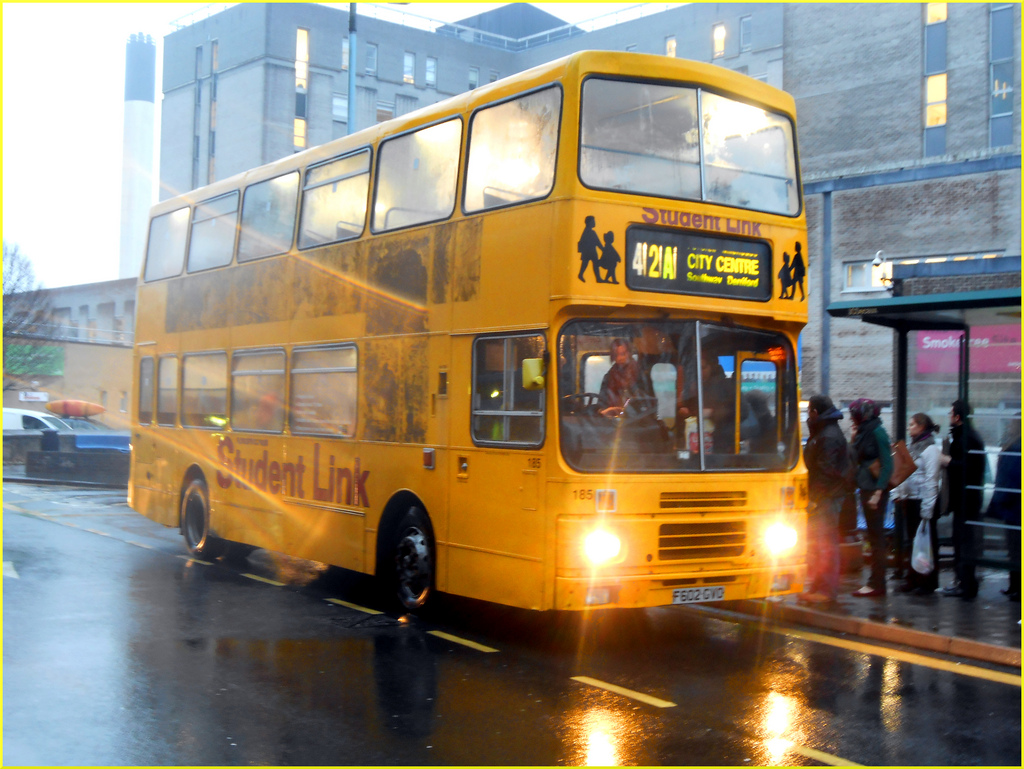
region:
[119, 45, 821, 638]
yellow double-decker bus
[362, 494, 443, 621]
black wheel on the yellow bus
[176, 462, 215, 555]
black wheel on the yellow bus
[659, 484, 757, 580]
grate on the yellow bus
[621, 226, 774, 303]
location sign on the top of the yellow bus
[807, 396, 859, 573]
person waiting to get on the bus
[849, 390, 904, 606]
person waiting to get on the bus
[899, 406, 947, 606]
person waiting to get on the bus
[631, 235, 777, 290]
yellow lcd on bus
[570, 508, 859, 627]
white lights on bus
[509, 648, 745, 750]
yellow lines on road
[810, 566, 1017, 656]
sidewalk is dark grey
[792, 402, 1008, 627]
people queued outside bus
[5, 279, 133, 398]
tan fence in distance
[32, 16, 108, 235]
grey and white sky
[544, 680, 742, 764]
Reflection of headlights on the road.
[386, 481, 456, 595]
Large black tire on the side of the bus.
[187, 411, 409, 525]
Bright red letters on the side of the yellow bus.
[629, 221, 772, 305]
Light colored yellow numbers on the front of the bus.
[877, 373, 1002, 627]
Two girls standing on the sidewalk.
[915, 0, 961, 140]
Two lit up windows on the side of the building.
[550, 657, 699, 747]
Unbroken yellow paint lines on the road.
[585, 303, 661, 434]
Person standing up on the bus.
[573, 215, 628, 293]
Painted people on the front of the bus.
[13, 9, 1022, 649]
picture taken during the day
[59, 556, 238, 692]
the road surface is wet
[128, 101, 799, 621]
the bus is yellow in color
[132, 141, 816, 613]
the bus is a double decker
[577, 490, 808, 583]
the buses' lights are on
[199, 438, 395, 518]
the bus says student link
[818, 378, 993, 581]
people are standing next to the bus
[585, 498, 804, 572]
two lights in front of the bus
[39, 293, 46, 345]
green leaves on the tree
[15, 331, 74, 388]
green leaves on the tree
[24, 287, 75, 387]
green leaves on the tree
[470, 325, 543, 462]
a window on a bus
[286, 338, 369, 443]
a window on a bus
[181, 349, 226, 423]
a window on a bus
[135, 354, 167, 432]
a window on a bus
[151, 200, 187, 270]
a window on a bus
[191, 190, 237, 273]
a window on a bus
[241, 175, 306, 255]
a window on a bus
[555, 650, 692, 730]
a small yellow line on the road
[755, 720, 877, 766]
a small yellow line on the road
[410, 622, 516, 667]
a small yellow line on the road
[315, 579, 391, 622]
a small yellow line on the road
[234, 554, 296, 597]
a small yellow line on the road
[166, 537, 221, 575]
a small yellow line on the road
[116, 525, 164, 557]
a small yellow line on the road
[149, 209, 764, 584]
big yellow bus on pavement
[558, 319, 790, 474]
frontal window of the bus below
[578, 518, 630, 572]
right side light of the bus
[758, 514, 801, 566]
left side light od the bus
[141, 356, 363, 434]
lateral glasses windows of the bus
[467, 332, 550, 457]
driver's window left side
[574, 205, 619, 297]
silhouette ad child and person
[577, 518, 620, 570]
the headlight of a bus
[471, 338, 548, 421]
a window on the bus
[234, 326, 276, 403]
a window on the bus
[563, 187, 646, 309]
people painted on front of bus